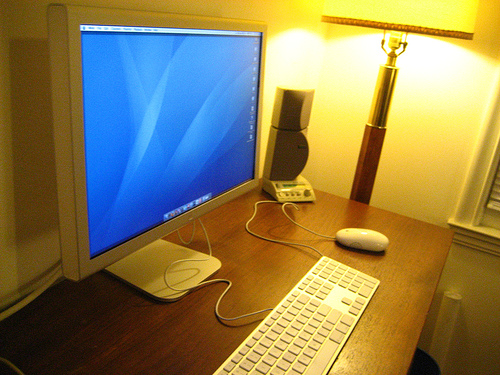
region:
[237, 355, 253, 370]
white button on keyboard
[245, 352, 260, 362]
white button on keyboard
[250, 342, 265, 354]
white button on keyboard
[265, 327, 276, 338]
white button on keyboard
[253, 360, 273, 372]
white button on keyboard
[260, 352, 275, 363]
white button on keyboard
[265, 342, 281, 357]
white button on keyboard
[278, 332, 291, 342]
white button on keyboard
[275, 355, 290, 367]
white button on keyboard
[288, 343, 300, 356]
white button on keyboard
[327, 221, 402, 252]
mouse on a desk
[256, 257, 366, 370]
key board on a desk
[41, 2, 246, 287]
monitor on a desk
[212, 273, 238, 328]
cord on a desk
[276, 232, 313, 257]
cord on a desk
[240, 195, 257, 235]
cord on a desk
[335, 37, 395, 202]
lamp next to desk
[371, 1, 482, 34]
lamp shade on a lamp pole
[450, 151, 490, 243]
window next to a desk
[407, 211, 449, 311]
desk next to window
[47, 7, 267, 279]
a white monitor on a desk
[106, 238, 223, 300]
a white monitor's stand on a desk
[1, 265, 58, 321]
a white wire against the wall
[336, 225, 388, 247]
a white wires computer mouse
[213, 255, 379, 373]
a white slim computer keyboard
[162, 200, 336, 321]
white wires on a desk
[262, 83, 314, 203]
a white and gray speaker on a desk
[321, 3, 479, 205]
a lamp in the corner of a room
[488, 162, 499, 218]
edge of white blinds on a window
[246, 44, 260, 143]
icons on a computer screen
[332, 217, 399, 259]
a mouse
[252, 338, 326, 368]
the keyboard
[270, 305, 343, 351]
the keyboard is white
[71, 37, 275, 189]
a computer monitor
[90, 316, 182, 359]
the desk is brown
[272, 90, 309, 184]
a speaker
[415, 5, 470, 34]
a lamp shade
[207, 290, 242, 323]
the cord is white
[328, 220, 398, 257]
the mouse is white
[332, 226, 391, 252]
the mouse is on the table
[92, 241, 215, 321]
white base of monitor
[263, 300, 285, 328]
white keyboard connected to monitor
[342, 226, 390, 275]
white mouse connected to computer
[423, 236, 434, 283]
computer sitting on desk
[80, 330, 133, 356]
desk is dark and light brown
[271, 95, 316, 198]
gray and white computer speaker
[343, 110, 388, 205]
lamp is brown and chrome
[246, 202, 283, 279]
white wires on desk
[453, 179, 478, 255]
white frame of window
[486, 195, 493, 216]
white blinds on window